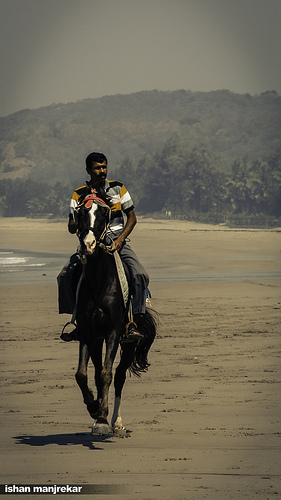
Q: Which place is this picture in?
A: It is at the beach.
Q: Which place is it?
A: It is a beach.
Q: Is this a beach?
A: Yes, it is a beach.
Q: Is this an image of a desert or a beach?
A: It is showing a beach.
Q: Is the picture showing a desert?
A: No, the picture is showing a beach.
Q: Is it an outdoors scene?
A: Yes, it is outdoors.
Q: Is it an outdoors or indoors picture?
A: It is outdoors.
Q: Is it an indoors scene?
A: No, it is outdoors.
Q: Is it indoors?
A: No, it is outdoors.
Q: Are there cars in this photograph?
A: No, there are no cars.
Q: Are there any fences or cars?
A: No, there are no cars or fences.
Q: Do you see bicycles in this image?
A: No, there are no bicycles.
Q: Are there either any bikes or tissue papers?
A: No, there are no bikes or tissue papers.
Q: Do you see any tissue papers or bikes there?
A: No, there are no bikes or tissue papers.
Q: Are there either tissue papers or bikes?
A: No, there are no bikes or tissue papers.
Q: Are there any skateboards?
A: No, there are no skateboards.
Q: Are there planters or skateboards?
A: No, there are no skateboards or planters.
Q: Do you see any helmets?
A: No, there are no helmets.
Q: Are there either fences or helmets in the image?
A: No, there are no helmets or fences.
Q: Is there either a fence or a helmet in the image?
A: No, there are no helmets or fences.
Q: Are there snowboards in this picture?
A: No, there are no snowboards.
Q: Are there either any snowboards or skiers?
A: No, there are no snowboards or skiers.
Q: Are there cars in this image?
A: No, there are no cars.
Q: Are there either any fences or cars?
A: No, there are no cars or fences.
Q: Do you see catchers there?
A: No, there are no catchers.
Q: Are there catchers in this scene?
A: No, there are no catchers.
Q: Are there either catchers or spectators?
A: No, there are no catchers or spectators.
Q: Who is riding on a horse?
A: The man is riding on a horse.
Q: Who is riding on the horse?
A: The man is riding on a horse.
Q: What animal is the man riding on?
A: The man is riding on a horse.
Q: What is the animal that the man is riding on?
A: The animal is a horse.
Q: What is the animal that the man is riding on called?
A: The animal is a horse.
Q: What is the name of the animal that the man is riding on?
A: The animal is a horse.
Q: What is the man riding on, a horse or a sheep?
A: The man is riding on a horse.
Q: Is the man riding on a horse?
A: Yes, the man is riding on a horse.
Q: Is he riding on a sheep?
A: No, the man is riding on a horse.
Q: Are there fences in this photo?
A: No, there are no fences.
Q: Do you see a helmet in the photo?
A: No, there are no helmets.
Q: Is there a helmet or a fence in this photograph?
A: No, there are no helmets or fences.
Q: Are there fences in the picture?
A: No, there are no fences.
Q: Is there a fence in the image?
A: No, there are no fences.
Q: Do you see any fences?
A: No, there are no fences.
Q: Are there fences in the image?
A: No, there are no fences.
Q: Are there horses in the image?
A: Yes, there is a horse.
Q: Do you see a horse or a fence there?
A: Yes, there is a horse.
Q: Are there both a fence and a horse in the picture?
A: No, there is a horse but no fences.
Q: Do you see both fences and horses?
A: No, there is a horse but no fences.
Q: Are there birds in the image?
A: No, there are no birds.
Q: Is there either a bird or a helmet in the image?
A: No, there are no birds or helmets.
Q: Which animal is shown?
A: The animal is a horse.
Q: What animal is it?
A: The animal is a horse.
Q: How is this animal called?
A: This is a horse.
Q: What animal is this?
A: This is a horse.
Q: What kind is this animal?
A: This is a horse.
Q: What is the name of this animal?
A: This is a horse.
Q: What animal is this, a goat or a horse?
A: This is a horse.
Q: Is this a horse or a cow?
A: This is a horse.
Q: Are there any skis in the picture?
A: No, there are no skis.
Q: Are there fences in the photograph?
A: No, there are no fences.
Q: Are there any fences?
A: No, there are no fences.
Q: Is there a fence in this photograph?
A: No, there are no fences.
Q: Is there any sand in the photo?
A: Yes, there is sand.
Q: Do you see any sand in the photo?
A: Yes, there is sand.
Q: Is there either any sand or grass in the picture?
A: Yes, there is sand.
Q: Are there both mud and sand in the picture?
A: No, there is sand but no mud.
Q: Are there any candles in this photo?
A: No, there are no candles.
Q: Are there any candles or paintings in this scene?
A: No, there are no candles or paintings.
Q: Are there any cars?
A: No, there are no cars.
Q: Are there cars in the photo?
A: No, there are no cars.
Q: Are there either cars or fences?
A: No, there are no cars or fences.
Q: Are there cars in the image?
A: No, there are no cars.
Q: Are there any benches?
A: No, there are no benches.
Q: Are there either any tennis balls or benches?
A: No, there are no benches or tennis balls.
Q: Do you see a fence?
A: No, there are no fences.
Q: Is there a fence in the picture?
A: No, there are no fences.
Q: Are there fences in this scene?
A: No, there are no fences.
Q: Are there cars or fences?
A: No, there are no fences or cars.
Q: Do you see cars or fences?
A: No, there are no fences or cars.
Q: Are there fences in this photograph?
A: No, there are no fences.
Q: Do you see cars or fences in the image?
A: No, there are no fences or cars.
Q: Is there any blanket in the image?
A: Yes, there is a blanket.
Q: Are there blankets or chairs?
A: Yes, there is a blanket.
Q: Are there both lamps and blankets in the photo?
A: No, there is a blanket but no lamps.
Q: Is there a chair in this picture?
A: No, there are no chairs.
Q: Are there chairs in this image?
A: No, there are no chairs.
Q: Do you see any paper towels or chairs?
A: No, there are no chairs or paper towels.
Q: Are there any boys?
A: No, there are no boys.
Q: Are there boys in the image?
A: No, there are no boys.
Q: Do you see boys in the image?
A: No, there are no boys.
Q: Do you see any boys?
A: No, there are no boys.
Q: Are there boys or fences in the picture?
A: No, there are no boys or fences.